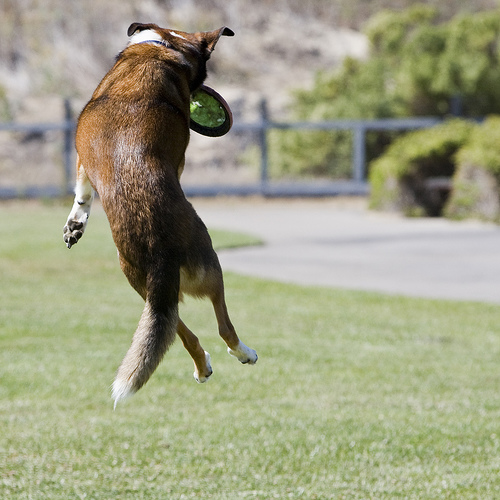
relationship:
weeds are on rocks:
[373, 116, 496, 173] [371, 123, 496, 222]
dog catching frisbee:
[61, 21, 259, 413] [176, 81, 238, 139]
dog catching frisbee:
[61, 21, 259, 413] [181, 73, 238, 138]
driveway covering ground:
[199, 200, 498, 300] [9, 197, 494, 497]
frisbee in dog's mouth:
[188, 84, 234, 138] [180, 52, 208, 96]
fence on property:
[0, 94, 445, 202] [24, 188, 466, 490]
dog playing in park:
[57, 20, 259, 420] [1, 0, 500, 500]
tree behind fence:
[260, 10, 480, 193] [7, 116, 473, 198]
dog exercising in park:
[57, 20, 259, 420] [1, 0, 500, 500]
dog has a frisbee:
[57, 20, 259, 420] [190, 82, 235, 139]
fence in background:
[0, 94, 445, 202] [8, 12, 482, 203]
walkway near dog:
[233, 165, 477, 302] [57, 20, 259, 420]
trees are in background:
[280, 18, 470, 202] [8, 12, 482, 203]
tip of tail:
[106, 382, 141, 400] [109, 255, 182, 413]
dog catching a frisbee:
[57, 20, 259, 420] [190, 83, 233, 135]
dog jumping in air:
[57, 20, 259, 420] [25, 14, 469, 434]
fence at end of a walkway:
[7, 96, 465, 200] [187, 194, 500, 304]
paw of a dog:
[62, 217, 82, 247] [57, 20, 259, 420]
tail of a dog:
[109, 255, 182, 413] [57, 20, 259, 420]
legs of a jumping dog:
[139, 280, 261, 384] [57, 20, 259, 420]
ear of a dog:
[194, 22, 239, 53] [55, 15, 272, 404]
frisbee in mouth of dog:
[187, 85, 232, 136] [61, 21, 259, 413]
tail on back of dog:
[110, 238, 181, 399] [61, 21, 259, 413]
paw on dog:
[62, 217, 82, 247] [61, 21, 259, 413]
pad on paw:
[61, 222, 89, 248] [62, 217, 82, 247]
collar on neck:
[130, 37, 197, 71] [125, 29, 208, 88]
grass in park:
[5, 191, 498, 499] [1, 0, 494, 499]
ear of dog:
[206, 22, 235, 49] [61, 21, 259, 413]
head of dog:
[118, 25, 233, 80] [61, 21, 259, 413]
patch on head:
[127, 30, 172, 50] [118, 25, 233, 80]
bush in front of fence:
[369, 123, 476, 218] [0, 94, 445, 202]